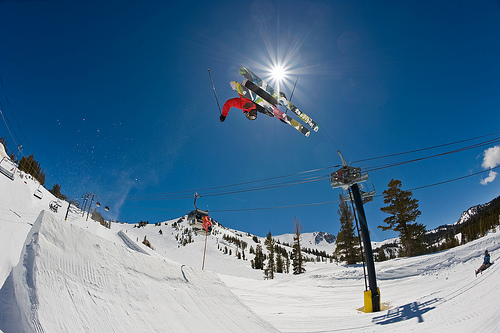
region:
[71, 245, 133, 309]
white snow on ground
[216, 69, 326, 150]
person doing trick in air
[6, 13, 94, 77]
white clouds on blue sky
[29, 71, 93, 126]
white clouds on blue sky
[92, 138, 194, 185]
white clouds on blue sky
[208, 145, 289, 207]
white clouds on blue sky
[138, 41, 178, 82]
white clouds on blue sky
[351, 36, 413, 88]
white clouds on blue sky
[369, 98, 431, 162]
white clouds on blue sky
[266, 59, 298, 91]
sun in sky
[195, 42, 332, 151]
airborne skiier against a blue sky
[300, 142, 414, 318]
support pole for ski lift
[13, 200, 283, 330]
half pipe for snowboarding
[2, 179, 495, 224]
ski lift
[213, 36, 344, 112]
lens flare caused by the sun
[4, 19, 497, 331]
outdoor facility for winter sports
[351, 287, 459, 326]
shadow cast on snow by overhead lift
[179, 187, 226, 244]
ski lift car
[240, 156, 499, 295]
row of trees alongside ski lift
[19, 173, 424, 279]
natural mountains at ski resort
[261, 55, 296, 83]
Sun in the sky.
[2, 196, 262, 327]
Ski ramp in the snow.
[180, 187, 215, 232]
Ski lift in the air.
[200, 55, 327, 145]
Skier in midair.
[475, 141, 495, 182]
White clouds in the sky.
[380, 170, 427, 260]
Tree in the background.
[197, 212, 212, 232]
Person sitting in ski lift.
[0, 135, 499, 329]
Snow covered ground.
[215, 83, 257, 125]
Red jacket on person.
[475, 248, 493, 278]
Person sitting on the snow.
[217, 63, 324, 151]
person doing tricks on board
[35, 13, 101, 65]
white clouds in blue sky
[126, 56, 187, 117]
white clouds in blue sky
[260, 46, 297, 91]
sun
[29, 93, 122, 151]
white clouds in blue sky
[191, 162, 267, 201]
white clouds in blue sky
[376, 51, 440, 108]
white clouds in blue sky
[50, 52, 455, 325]
this skier is high in the air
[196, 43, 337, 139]
he looks like he is near the sun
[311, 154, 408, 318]
part of a ski lift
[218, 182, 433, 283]
trees in the resort area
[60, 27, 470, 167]
clear skies above the course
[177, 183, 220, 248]
a chair on the ski lift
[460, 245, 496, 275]
a person on the slopes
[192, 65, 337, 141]
this skier is doing stunts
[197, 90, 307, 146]
he has on a red ski jacket